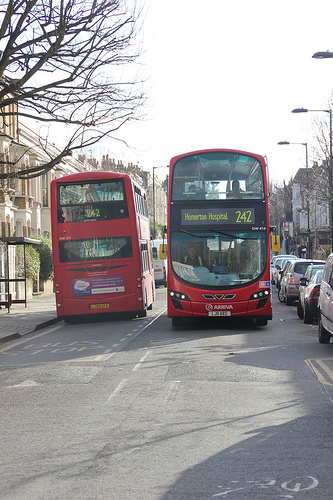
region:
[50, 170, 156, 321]
A leaning red double decker bus driving away.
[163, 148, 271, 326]
An oncoming double decker bus with male driver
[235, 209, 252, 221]
The number 242 on the front of a bus.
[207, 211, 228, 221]
The yellow word Hospital on the front of a bus.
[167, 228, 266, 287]
The front bottom windshield of a double decker bus.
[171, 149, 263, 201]
The front top window of a double decker bus.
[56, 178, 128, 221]
A top back window of a double decker bus.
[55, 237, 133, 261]
The back bottom window of a double decker bus.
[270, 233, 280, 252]
A yellow rear view mirror hanging down to the right of an oncoming bus.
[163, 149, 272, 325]
A very large double decker bus with a male driver.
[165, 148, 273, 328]
red bus on street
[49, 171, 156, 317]
double decker bus on street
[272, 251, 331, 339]
cars parked by curb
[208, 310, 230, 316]
white license plate on bus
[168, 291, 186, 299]
head lights on bus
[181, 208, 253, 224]
destination sign on bus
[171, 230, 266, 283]
wind shield on bus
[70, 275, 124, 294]
purple and white sign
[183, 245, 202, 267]
man driving red bus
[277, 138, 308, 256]
street lamp on pole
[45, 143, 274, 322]
two red buses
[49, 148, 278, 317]
two double deck buses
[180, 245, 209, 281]
driver of the double decker bus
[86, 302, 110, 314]
black and yellow rear license plate of bus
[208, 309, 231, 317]
black and white front license plate of bus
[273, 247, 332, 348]
cars parked along the street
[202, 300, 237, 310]
white lettering on red bus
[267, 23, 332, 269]
three street lights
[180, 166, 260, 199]
people riding on second level of double deck bus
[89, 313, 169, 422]
white lines painted on the road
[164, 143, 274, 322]
a red bus on the street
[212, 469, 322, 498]
a bicycle mark on the pavement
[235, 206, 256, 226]
a number on the bus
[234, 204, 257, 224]
the bus number is 242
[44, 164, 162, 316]
a bus going down the street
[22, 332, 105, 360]
a bus stop on the street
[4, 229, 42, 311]
a bus stop shelter by the street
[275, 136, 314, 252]
a telephone pole on the sidewalk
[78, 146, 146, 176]
chimneys on a building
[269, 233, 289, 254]
a yellow sign on the sidewalk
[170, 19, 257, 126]
this is the sky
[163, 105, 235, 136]
the sky is blue in color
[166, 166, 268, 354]
this is a bus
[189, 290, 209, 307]
the bus is red in color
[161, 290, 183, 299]
this is the head lump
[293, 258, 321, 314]
this is a car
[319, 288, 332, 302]
the car is white in color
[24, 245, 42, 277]
this is a tree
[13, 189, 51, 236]
this is a building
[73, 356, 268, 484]
this is the road